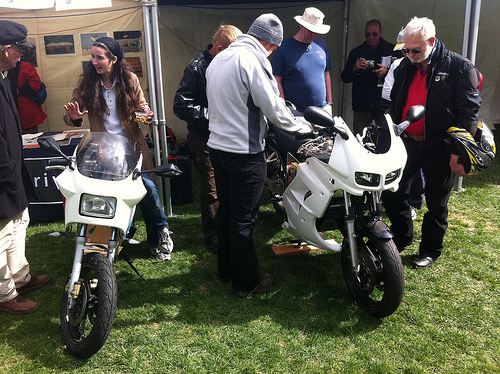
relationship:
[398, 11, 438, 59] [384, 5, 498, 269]
hair on man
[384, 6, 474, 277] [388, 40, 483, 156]
man wearing coat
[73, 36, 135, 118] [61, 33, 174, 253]
hair belonging to woman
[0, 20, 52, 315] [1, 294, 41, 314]
guy wearing shoe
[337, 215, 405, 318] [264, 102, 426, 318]
wheel mounted on motorcycle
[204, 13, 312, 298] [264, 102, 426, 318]
man looking at motorcycle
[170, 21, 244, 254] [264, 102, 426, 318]
person looking at motorcycle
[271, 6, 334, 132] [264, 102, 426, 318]
man looking at motorcycle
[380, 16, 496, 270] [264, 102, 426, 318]
man looking at motorcycle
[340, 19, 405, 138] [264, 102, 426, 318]
guy looking at motorcycle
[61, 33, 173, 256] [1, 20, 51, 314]
girl talking to guy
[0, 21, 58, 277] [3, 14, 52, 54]
guy in hat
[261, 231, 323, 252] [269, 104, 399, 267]
wood by motorcycle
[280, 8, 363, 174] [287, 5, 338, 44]
man in hat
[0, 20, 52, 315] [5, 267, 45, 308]
guy in shoes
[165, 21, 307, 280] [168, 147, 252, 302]
man in pants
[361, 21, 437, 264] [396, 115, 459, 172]
man in belt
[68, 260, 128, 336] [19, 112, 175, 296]
wheel on bike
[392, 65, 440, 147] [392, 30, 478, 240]
shirt on man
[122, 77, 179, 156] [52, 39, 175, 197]
coat on woman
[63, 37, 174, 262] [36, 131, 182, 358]
girl on bike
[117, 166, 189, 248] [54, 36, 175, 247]
jeans on woman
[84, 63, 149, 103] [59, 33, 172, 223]
scarf on woman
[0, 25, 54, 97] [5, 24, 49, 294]
hat on man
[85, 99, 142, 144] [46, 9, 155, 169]
shirt on woman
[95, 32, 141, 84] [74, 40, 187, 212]
hair on woman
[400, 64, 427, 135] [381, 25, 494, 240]
shirt on man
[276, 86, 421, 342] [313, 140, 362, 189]
motorcycle seen part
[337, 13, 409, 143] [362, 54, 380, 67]
guy holding camera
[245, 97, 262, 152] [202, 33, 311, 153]
stripe on jacket